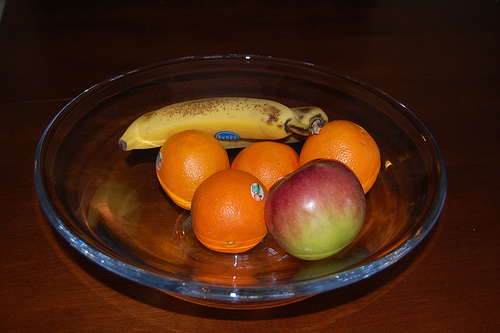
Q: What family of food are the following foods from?
A: Fruit.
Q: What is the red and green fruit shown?
A: Apple.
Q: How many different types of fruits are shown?
A: Three.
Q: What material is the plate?
A: Glass.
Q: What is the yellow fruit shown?
A: Banana.